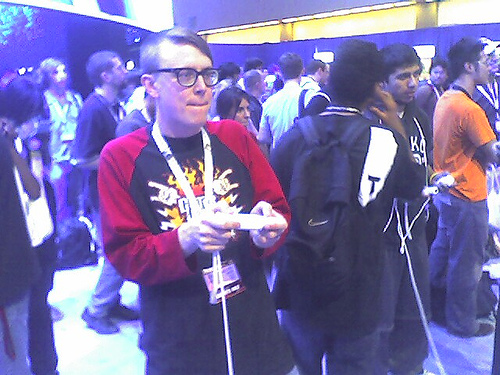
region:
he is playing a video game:
[87, 23, 313, 372]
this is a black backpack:
[289, 110, 384, 337]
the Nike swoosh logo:
[301, 215, 334, 230]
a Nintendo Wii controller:
[212, 203, 284, 235]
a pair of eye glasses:
[146, 64, 227, 91]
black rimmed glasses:
[151, 58, 230, 91]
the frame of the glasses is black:
[140, 62, 225, 95]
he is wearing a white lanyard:
[140, 108, 257, 309]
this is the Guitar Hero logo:
[169, 177, 226, 232]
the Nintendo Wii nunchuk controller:
[417, 163, 462, 203]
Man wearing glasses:
[135, 60, 222, 90]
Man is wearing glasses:
[139, 62, 225, 91]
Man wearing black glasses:
[134, 59, 229, 94]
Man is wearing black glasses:
[136, 60, 221, 88]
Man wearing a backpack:
[266, 105, 390, 316]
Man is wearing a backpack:
[280, 110, 377, 306]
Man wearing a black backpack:
[268, 102, 376, 322]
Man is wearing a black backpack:
[280, 111, 382, 309]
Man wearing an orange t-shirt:
[430, 82, 499, 207]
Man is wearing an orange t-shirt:
[423, 80, 498, 203]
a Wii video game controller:
[222, 213, 267, 230]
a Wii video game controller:
[419, 185, 437, 196]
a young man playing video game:
[97, 27, 299, 372]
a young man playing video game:
[372, 40, 454, 371]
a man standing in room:
[65, 48, 140, 335]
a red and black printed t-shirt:
[92, 120, 293, 370]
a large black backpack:
[279, 105, 379, 335]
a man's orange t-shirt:
[432, 91, 496, 202]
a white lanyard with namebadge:
[151, 122, 247, 307]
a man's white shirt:
[259, 80, 319, 146]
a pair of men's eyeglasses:
[148, 66, 220, 88]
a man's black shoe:
[79, 307, 116, 334]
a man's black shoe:
[107, 303, 137, 319]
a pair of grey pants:
[426, 191, 490, 337]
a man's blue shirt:
[43, 89, 81, 165]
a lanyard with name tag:
[48, 99, 75, 141]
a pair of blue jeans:
[0, 294, 30, 373]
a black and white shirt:
[268, 110, 437, 327]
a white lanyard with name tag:
[477, 80, 498, 132]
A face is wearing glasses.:
[155, 65, 222, 126]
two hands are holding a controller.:
[190, 200, 285, 242]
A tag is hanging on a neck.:
[147, 117, 242, 298]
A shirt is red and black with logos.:
[90, 120, 290, 362]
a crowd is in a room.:
[0, 35, 497, 370]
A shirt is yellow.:
[430, 90, 491, 200]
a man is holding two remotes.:
[380, 43, 451, 198]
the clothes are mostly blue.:
[1, 128, 56, 368]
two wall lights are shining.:
[315, 0, 433, 63]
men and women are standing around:
[0, 37, 498, 122]